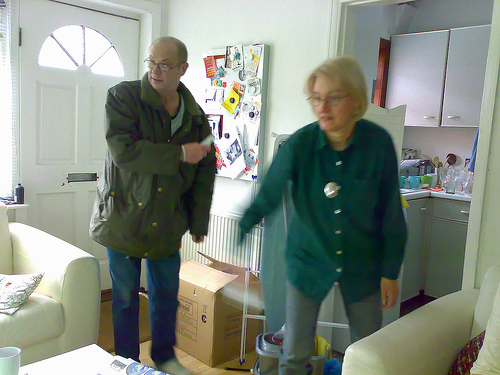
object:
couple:
[88, 36, 409, 374]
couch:
[338, 264, 499, 374]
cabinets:
[423, 188, 470, 298]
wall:
[401, 126, 474, 168]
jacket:
[89, 72, 217, 261]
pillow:
[0, 272, 47, 314]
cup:
[0, 345, 24, 374]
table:
[18, 343, 166, 374]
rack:
[179, 208, 265, 279]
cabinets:
[384, 24, 491, 128]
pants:
[278, 278, 383, 374]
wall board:
[198, 42, 270, 183]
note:
[203, 55, 219, 78]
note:
[220, 87, 242, 114]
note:
[202, 87, 217, 101]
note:
[246, 77, 263, 96]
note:
[217, 124, 247, 179]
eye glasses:
[143, 54, 181, 72]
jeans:
[106, 247, 181, 365]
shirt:
[237, 118, 409, 303]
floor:
[97, 291, 252, 374]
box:
[175, 250, 263, 367]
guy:
[88, 35, 218, 374]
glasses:
[305, 93, 351, 106]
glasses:
[443, 166, 458, 195]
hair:
[303, 56, 369, 125]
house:
[0, 0, 498, 374]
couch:
[0, 201, 102, 365]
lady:
[235, 55, 409, 373]